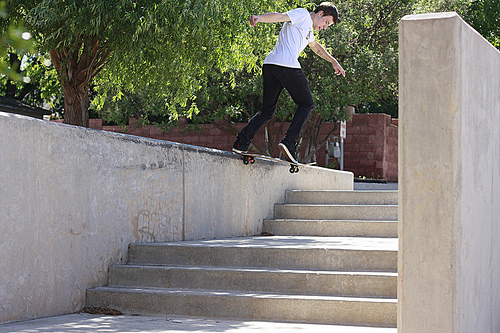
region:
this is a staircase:
[259, 197, 351, 331]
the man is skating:
[234, 1, 348, 163]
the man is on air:
[218, 4, 369, 159]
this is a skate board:
[251, 150, 281, 166]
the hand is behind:
[245, 5, 278, 28]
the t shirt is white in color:
[278, 27, 298, 57]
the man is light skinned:
[315, 45, 320, 50]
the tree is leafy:
[120, 10, 206, 102]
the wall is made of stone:
[397, 32, 464, 285]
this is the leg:
[276, 137, 296, 157]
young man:
[231, 0, 350, 165]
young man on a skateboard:
[237, 1, 347, 173]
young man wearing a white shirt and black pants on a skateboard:
[228, 0, 349, 177]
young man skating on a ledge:
[134, 0, 403, 310]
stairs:
[93, 161, 400, 323]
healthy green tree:
[1, 0, 228, 121]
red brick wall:
[203, 120, 405, 185]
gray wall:
[399, 18, 499, 331]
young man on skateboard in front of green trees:
[231, 2, 399, 184]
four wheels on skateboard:
[222, 133, 318, 177]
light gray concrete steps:
[82, 132, 397, 325]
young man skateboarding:
[211, 3, 360, 177]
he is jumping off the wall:
[215, 0, 350, 177]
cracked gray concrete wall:
[0, 116, 362, 324]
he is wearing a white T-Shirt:
[221, 5, 349, 183]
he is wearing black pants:
[221, 1, 362, 198]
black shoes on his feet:
[225, 123, 325, 183]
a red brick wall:
[94, 100, 396, 191]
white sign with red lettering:
[330, 109, 357, 189]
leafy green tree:
[30, 0, 234, 155]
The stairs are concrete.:
[121, 166, 442, 306]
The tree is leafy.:
[16, 2, 246, 110]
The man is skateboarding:
[15, 12, 457, 243]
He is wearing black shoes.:
[207, 108, 328, 187]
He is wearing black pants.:
[236, 44, 324, 186]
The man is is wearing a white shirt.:
[248, 3, 338, 108]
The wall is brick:
[173, 103, 398, 176]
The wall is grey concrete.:
[366, 10, 498, 330]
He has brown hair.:
[305, 3, 339, 30]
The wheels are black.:
[232, 149, 311, 182]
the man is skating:
[246, 2, 438, 264]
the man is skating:
[227, 8, 314, 262]